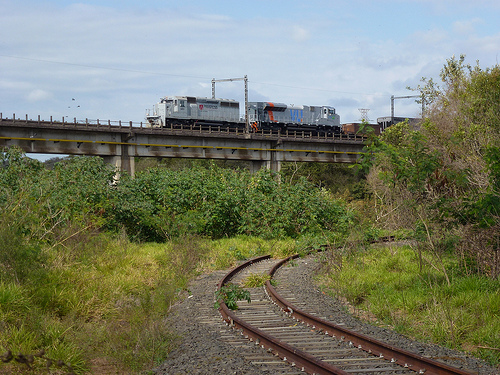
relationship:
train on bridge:
[144, 94, 424, 135] [1, 113, 377, 181]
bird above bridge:
[77, 104, 80, 108] [1, 113, 377, 181]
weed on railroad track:
[214, 281, 252, 311] [219, 251, 434, 372]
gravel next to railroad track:
[291, 263, 330, 307] [219, 251, 434, 372]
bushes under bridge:
[110, 165, 358, 240] [1, 113, 377, 181]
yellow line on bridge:
[0, 136, 378, 156] [1, 113, 377, 181]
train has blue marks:
[144, 94, 424, 135] [290, 108, 304, 123]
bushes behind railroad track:
[110, 165, 358, 240] [219, 251, 434, 372]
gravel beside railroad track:
[291, 263, 330, 307] [219, 251, 434, 372]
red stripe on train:
[268, 101, 274, 121] [144, 94, 424, 135]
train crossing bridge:
[144, 94, 424, 135] [1, 113, 377, 181]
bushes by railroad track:
[110, 165, 358, 240] [219, 251, 434, 372]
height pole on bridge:
[243, 76, 251, 134] [1, 113, 377, 181]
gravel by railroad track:
[291, 263, 330, 307] [219, 251, 434, 372]